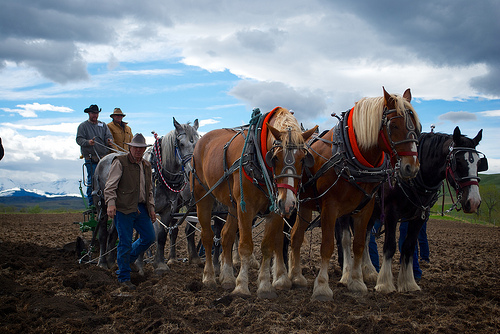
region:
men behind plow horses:
[74, 101, 486, 297]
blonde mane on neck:
[335, 96, 385, 180]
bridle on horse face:
[268, 149, 308, 204]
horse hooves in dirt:
[210, 277, 345, 315]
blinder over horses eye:
[469, 143, 498, 179]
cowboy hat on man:
[78, 99, 106, 121]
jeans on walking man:
[112, 199, 161, 283]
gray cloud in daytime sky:
[403, 6, 488, 63]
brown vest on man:
[110, 150, 154, 220]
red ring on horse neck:
[342, 118, 375, 175]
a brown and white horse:
[188, 111, 300, 296]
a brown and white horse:
[308, 83, 413, 296]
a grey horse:
[143, 108, 199, 272]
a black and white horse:
[364, 117, 487, 295]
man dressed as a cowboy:
[105, 130, 155, 283]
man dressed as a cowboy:
[73, 103, 113, 163]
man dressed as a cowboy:
[106, 104, 134, 150]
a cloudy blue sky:
[8, 1, 493, 187]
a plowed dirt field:
[13, 215, 499, 325]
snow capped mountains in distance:
[1, 186, 83, 201]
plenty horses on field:
[41, 31, 466, 301]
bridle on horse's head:
[380, 105, 420, 171]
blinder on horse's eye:
[475, 155, 490, 170]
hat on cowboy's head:
[125, 130, 152, 152]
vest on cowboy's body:
[112, 151, 159, 212]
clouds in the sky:
[0, 4, 495, 161]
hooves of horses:
[195, 261, 424, 296]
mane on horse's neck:
[351, 98, 391, 145]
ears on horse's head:
[380, 86, 419, 111]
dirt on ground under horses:
[0, 267, 493, 314]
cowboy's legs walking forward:
[109, 205, 157, 281]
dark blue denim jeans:
[114, 205, 156, 285]